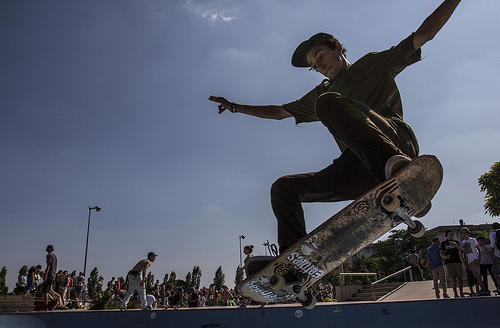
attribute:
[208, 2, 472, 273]
guy — performing, young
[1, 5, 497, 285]
sky — blue, clear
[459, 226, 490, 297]
person — young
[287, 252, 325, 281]
letters — white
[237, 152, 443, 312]
skateboard — ridden, up, tan, black, brown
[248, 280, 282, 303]
letters — white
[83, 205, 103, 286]
street light — above, grey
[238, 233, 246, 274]
light posts — behind, grey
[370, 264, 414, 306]
rails — support, metal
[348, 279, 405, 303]
stairs — concrete, brown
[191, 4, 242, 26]
cloud — small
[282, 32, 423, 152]
shirt — black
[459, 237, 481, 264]
shirt — white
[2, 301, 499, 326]
ground — grey